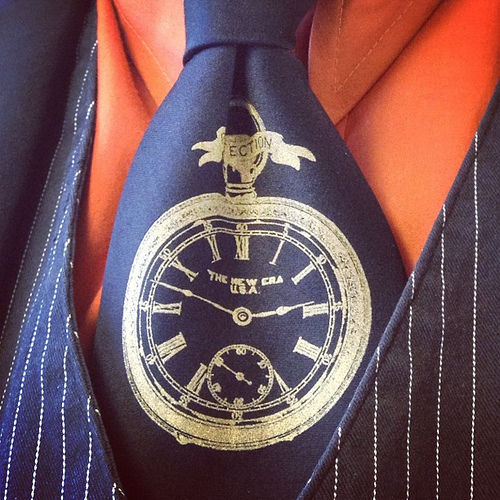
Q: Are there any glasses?
A: No, there are no glasses.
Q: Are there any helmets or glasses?
A: No, there are no glasses or helmets.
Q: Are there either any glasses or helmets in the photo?
A: No, there are no glasses or helmets.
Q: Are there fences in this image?
A: No, there are no fences.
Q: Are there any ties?
A: Yes, there is a tie.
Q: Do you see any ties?
A: Yes, there is a tie.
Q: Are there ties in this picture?
A: Yes, there is a tie.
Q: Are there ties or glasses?
A: Yes, there is a tie.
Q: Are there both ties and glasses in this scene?
A: No, there is a tie but no glasses.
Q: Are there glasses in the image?
A: No, there are no glasses.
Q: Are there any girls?
A: No, there are no girls.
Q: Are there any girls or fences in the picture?
A: No, there are no girls or fences.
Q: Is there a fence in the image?
A: No, there are no fences.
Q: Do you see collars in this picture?
A: Yes, there is a collar.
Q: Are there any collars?
A: Yes, there is a collar.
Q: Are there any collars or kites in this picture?
A: Yes, there is a collar.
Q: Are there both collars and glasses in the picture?
A: No, there is a collar but no glasses.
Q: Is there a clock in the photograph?
A: Yes, there is a clock.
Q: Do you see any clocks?
A: Yes, there is a clock.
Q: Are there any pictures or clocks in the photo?
A: Yes, there is a clock.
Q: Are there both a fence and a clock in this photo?
A: No, there is a clock but no fences.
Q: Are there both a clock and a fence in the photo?
A: No, there is a clock but no fences.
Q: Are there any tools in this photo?
A: No, there are no tools.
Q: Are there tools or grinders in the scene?
A: No, there are no tools or grinders.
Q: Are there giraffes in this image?
A: No, there are no giraffes.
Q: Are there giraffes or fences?
A: No, there are no giraffes or fences.